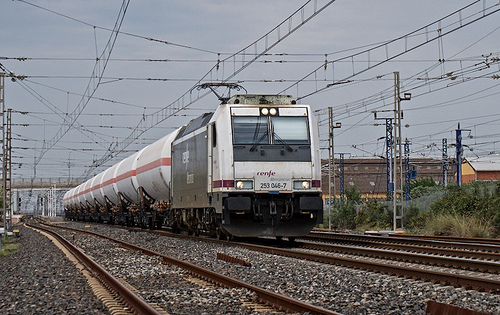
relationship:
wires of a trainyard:
[11, 10, 480, 176] [20, 96, 479, 296]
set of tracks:
[28, 195, 303, 306] [25, 209, 308, 304]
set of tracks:
[22, 195, 345, 315] [25, 209, 308, 304]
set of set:
[278, 238, 468, 279] [22, 195, 345, 315]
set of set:
[330, 216, 468, 252] [225, 239, 500, 292]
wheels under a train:
[62, 201, 306, 236] [60, 82, 330, 237]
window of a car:
[228, 115, 310, 166] [168, 75, 336, 239]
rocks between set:
[40, 232, 447, 302] [296, 216, 500, 250]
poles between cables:
[6, 65, 23, 238] [10, 20, 85, 170]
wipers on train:
[269, 119, 295, 159] [60, 82, 330, 237]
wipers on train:
[248, 126, 269, 152] [60, 82, 330, 237]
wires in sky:
[11, 9, 473, 160] [9, 10, 482, 200]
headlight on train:
[298, 177, 310, 194] [60, 82, 330, 237]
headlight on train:
[234, 177, 254, 190] [60, 82, 330, 237]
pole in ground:
[371, 107, 403, 208] [12, 200, 482, 305]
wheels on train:
[63, 204, 301, 244] [60, 82, 330, 237]